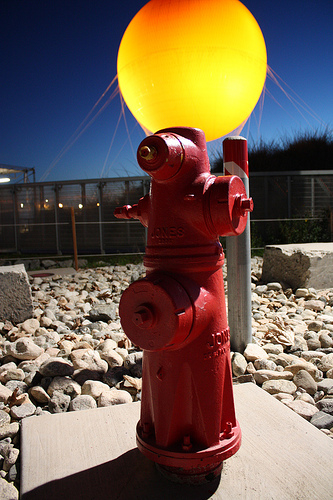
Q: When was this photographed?
A: Daytime.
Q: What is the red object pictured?
A: Fire hydrant.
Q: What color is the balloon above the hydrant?
A: Yellow.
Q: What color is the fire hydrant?
A: Red.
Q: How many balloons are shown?
A: One.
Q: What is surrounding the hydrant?
A: Stones.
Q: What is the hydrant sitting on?
A: Cement.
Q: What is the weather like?
A: Clear.